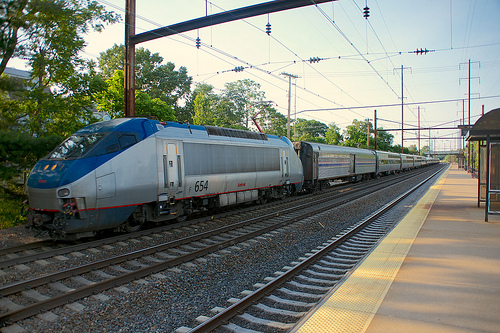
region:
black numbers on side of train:
[184, 171, 214, 196]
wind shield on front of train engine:
[49, 120, 126, 163]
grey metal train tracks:
[92, 246, 217, 286]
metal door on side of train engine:
[150, 137, 194, 219]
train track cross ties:
[261, 299, 293, 331]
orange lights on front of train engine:
[31, 162, 69, 182]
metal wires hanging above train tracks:
[178, 5, 483, 93]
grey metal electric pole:
[392, 58, 421, 146]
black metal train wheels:
[115, 203, 155, 234]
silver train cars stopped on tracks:
[295, 140, 452, 182]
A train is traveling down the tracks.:
[8, 52, 440, 258]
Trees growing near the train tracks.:
[1, 7, 396, 148]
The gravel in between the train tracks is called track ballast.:
[115, 228, 298, 324]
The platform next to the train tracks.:
[321, 153, 491, 330]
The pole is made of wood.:
[117, 0, 139, 113]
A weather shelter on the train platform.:
[463, 105, 498, 222]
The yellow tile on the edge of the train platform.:
[296, 158, 452, 330]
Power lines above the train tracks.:
[141, 2, 461, 73]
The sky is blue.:
[395, 5, 450, 36]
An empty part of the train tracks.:
[93, 235, 306, 330]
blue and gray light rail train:
[0, 110, 220, 226]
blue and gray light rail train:
[148, 133, 267, 201]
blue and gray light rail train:
[258, 144, 311, 182]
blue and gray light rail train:
[68, 122, 296, 207]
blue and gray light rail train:
[297, 136, 376, 179]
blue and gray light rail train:
[355, 148, 404, 179]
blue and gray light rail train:
[376, 148, 427, 175]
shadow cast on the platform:
[358, 191, 475, 318]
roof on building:
[473, 107, 488, 134]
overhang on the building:
[453, 132, 482, 144]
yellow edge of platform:
[332, 235, 423, 296]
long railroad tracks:
[203, 210, 336, 275]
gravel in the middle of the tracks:
[275, 235, 307, 255]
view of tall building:
[11, 57, 52, 92]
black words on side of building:
[188, 175, 226, 193]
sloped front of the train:
[33, 113, 170, 207]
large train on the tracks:
[53, 126, 435, 206]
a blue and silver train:
[20, 116, 312, 240]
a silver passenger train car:
[300, 140, 375, 185]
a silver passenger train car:
[372, 149, 399, 174]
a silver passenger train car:
[399, 150, 415, 171]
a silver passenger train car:
[415, 153, 426, 165]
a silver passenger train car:
[425, 155, 437, 163]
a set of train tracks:
[190, 161, 450, 328]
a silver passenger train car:
[1, 161, 441, 329]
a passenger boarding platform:
[297, 158, 495, 329]